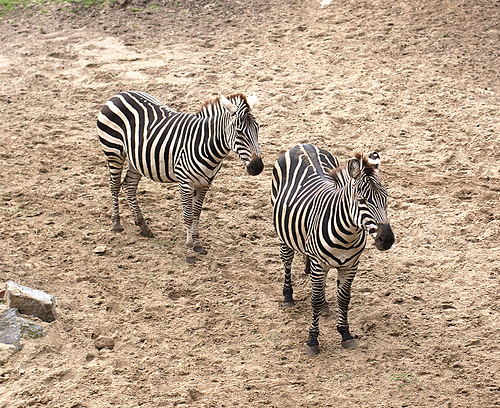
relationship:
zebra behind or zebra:
[94, 86, 266, 267] [262, 140, 401, 349]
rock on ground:
[3, 303, 24, 370] [2, 2, 494, 405]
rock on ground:
[5, 277, 56, 324] [2, 2, 494, 405]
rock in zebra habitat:
[3, 303, 24, 370] [3, 1, 495, 406]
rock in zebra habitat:
[5, 277, 56, 324] [3, 1, 495, 406]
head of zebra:
[218, 90, 266, 177] [270, 137, 397, 351]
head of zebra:
[346, 148, 401, 253] [88, 72, 266, 273]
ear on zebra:
[361, 136, 396, 176] [240, 123, 441, 360]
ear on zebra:
[318, 146, 360, 191] [240, 123, 441, 360]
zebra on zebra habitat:
[270, 137, 397, 351] [3, 1, 495, 406]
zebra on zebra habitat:
[94, 86, 266, 267] [3, 1, 495, 406]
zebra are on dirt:
[270, 137, 395, 354] [0, 0, 499, 406]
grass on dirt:
[382, 365, 422, 387] [0, 0, 499, 406]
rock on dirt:
[93, 334, 120, 357] [152, 301, 212, 353]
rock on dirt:
[5, 277, 56, 324] [0, 0, 499, 406]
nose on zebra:
[246, 159, 265, 172] [270, 137, 397, 351]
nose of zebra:
[371, 223, 395, 253] [223, 103, 479, 403]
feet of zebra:
[291, 325, 371, 354] [270, 137, 397, 351]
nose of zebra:
[246, 152, 267, 176] [88, 72, 266, 273]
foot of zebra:
[192, 242, 211, 256] [270, 137, 397, 351]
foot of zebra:
[183, 252, 195, 264] [94, 86, 266, 267]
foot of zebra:
[134, 224, 156, 236] [270, 137, 397, 351]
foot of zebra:
[109, 223, 123, 235] [94, 86, 266, 267]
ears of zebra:
[346, 149, 388, 178] [270, 137, 397, 351]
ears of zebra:
[217, 89, 257, 114] [94, 86, 266, 267]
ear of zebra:
[217, 89, 234, 119] [75, 64, 252, 254]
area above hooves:
[335, 322, 353, 342] [303, 339, 363, 354]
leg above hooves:
[306, 260, 330, 352] [284, 298, 295, 308]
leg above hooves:
[281, 236, 296, 304] [284, 298, 295, 308]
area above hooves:
[283, 282, 293, 295] [303, 339, 363, 354]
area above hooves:
[283, 282, 293, 295] [284, 298, 295, 308]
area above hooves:
[308, 330, 320, 345] [284, 298, 295, 308]